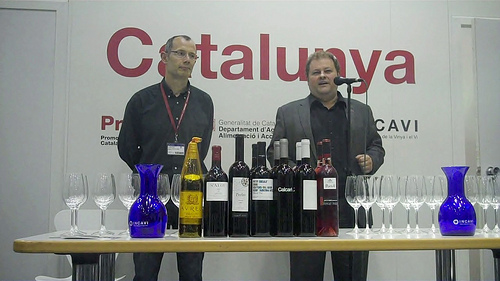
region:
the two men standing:
[118, 34, 385, 279]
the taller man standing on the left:
[117, 33, 215, 279]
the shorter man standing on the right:
[266, 52, 386, 279]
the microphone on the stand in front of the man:
[332, 75, 368, 277]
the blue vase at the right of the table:
[438, 166, 475, 234]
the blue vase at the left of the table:
[128, 165, 168, 237]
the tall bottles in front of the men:
[181, 133, 339, 238]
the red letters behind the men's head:
[106, 28, 415, 94]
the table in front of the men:
[13, 228, 498, 253]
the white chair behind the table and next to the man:
[33, 208, 125, 278]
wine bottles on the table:
[176, 122, 338, 242]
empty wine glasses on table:
[341, 169, 376, 224]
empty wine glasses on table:
[346, 159, 418, 247]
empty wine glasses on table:
[46, 158, 173, 250]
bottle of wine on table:
[181, 135, 203, 238]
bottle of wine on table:
[211, 141, 231, 236]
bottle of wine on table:
[233, 134, 248, 236]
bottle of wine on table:
[255, 143, 275, 243]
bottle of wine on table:
[271, 137, 304, 243]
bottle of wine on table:
[299, 135, 311, 237]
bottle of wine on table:
[321, 139, 339, 237]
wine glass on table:
[64, 173, 83, 233]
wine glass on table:
[361, 177, 373, 236]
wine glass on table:
[347, 180, 364, 239]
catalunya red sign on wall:
[89, 13, 442, 100]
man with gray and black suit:
[259, 65, 392, 165]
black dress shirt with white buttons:
[127, 90, 239, 162]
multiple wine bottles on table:
[208, 142, 349, 232]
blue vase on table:
[410, 148, 485, 250]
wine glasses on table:
[343, 164, 439, 235]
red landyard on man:
[149, 94, 205, 167]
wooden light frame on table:
[17, 235, 498, 247]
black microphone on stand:
[326, 65, 374, 220]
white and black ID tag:
[162, 140, 177, 153]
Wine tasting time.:
[18, 17, 490, 267]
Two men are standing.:
[102, 57, 460, 149]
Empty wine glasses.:
[334, 163, 435, 215]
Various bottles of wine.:
[168, 127, 350, 225]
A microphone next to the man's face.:
[335, 65, 372, 143]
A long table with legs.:
[30, 220, 498, 258]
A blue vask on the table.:
[132, 164, 176, 251]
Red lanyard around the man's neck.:
[157, 84, 194, 125]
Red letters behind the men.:
[97, 23, 458, 110]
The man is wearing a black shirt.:
[320, 113, 334, 137]